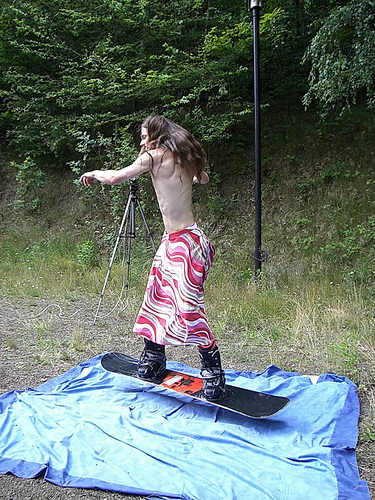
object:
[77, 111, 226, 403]
person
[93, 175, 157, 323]
camera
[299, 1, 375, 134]
branches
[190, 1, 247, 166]
branches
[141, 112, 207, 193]
hair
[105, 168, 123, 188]
elbows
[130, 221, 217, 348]
skirt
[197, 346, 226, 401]
boots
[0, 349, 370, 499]
blanket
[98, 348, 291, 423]
snowboard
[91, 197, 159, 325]
tripod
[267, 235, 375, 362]
grass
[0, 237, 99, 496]
ground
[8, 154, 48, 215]
plants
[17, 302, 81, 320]
cable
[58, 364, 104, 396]
wrinkles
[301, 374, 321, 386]
pad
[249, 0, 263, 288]
pole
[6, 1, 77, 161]
tree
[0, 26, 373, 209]
hill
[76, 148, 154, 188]
left arm